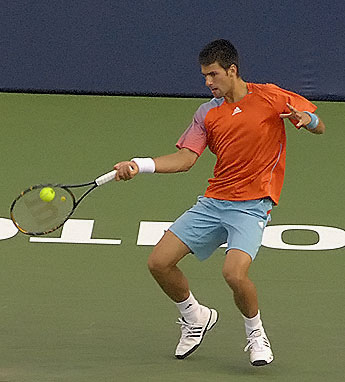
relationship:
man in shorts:
[110, 35, 327, 370] [165, 190, 274, 264]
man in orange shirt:
[113, 39, 326, 367] [176, 82, 317, 202]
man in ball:
[110, 35, 327, 370] [39, 187, 56, 203]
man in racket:
[113, 39, 326, 367] [11, 163, 133, 234]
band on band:
[130, 157, 155, 174] [130, 157, 155, 174]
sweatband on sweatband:
[301, 105, 318, 130] [303, 111, 318, 130]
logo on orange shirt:
[231, 105, 242, 118] [176, 82, 317, 202]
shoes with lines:
[233, 314, 278, 366] [262, 334, 269, 346]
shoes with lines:
[233, 314, 278, 366] [261, 342, 272, 349]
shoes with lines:
[169, 305, 221, 359] [182, 331, 203, 338]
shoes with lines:
[169, 305, 221, 359] [184, 327, 204, 333]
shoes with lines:
[169, 305, 221, 359] [187, 322, 204, 329]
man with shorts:
[110, 35, 327, 370] [168, 195, 272, 262]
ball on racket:
[39, 187, 56, 203] [8, 169, 122, 233]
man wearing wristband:
[113, 39, 326, 367] [131, 154, 156, 172]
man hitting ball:
[113, 39, 326, 367] [35, 177, 58, 208]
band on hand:
[130, 157, 155, 174] [112, 158, 138, 181]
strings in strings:
[24, 188, 58, 226] [10, 184, 73, 234]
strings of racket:
[10, 184, 73, 234] [11, 163, 133, 234]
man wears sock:
[110, 35, 327, 370] [172, 286, 202, 326]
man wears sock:
[110, 35, 327, 370] [237, 308, 265, 337]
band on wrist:
[130, 148, 156, 188] [110, 138, 175, 204]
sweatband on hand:
[303, 111, 318, 130] [277, 103, 322, 145]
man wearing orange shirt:
[110, 35, 327, 370] [175, 82, 314, 205]